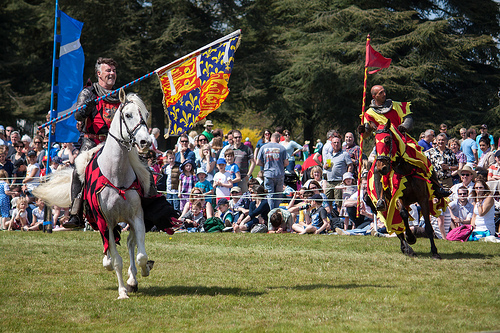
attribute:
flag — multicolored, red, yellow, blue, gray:
[41, 29, 243, 131]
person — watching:
[328, 135, 354, 185]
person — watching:
[228, 126, 248, 175]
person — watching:
[425, 129, 455, 172]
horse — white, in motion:
[51, 92, 160, 299]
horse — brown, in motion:
[365, 110, 442, 259]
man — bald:
[360, 88, 419, 169]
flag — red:
[363, 41, 394, 75]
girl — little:
[208, 154, 233, 203]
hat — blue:
[216, 156, 227, 169]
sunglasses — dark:
[231, 135, 244, 141]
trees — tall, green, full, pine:
[2, 2, 500, 143]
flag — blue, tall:
[49, 6, 93, 164]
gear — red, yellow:
[369, 120, 451, 224]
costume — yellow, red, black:
[361, 103, 429, 170]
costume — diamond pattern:
[74, 154, 180, 242]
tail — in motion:
[34, 170, 78, 201]